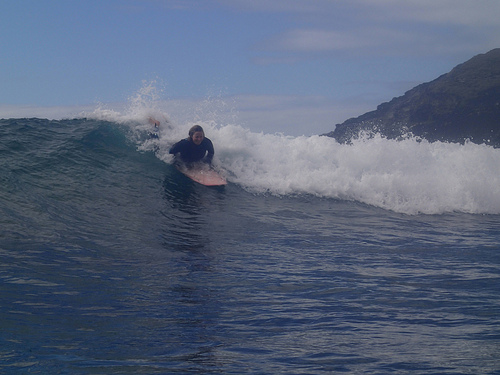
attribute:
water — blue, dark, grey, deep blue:
[5, 118, 499, 374]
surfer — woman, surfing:
[169, 124, 216, 168]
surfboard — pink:
[166, 160, 230, 191]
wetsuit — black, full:
[166, 140, 215, 164]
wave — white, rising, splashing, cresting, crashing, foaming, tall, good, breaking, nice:
[114, 106, 498, 214]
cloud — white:
[285, 27, 374, 54]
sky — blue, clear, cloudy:
[1, 3, 499, 122]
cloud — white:
[371, 2, 500, 24]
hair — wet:
[190, 125, 205, 137]